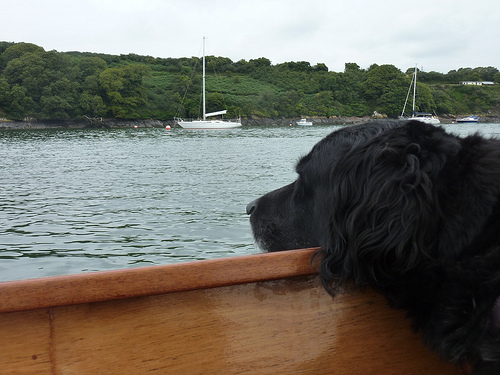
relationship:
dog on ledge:
[239, 115, 497, 365] [2, 245, 333, 314]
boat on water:
[5, 242, 464, 374] [0, 124, 498, 278]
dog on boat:
[239, 115, 497, 365] [5, 242, 464, 374]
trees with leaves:
[5, 46, 154, 119] [60, 89, 68, 90]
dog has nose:
[239, 115, 497, 365] [242, 194, 267, 222]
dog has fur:
[239, 115, 497, 365] [344, 161, 428, 242]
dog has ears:
[239, 115, 497, 365] [323, 144, 443, 289]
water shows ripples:
[0, 124, 498, 278] [14, 180, 166, 240]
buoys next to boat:
[127, 121, 174, 133] [176, 31, 246, 128]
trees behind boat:
[5, 46, 154, 119] [176, 31, 246, 128]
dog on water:
[239, 115, 497, 365] [0, 124, 498, 278]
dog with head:
[239, 115, 497, 365] [234, 113, 450, 286]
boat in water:
[176, 31, 246, 128] [0, 124, 498, 278]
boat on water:
[176, 31, 246, 128] [0, 124, 498, 278]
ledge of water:
[2, 245, 333, 314] [0, 124, 498, 278]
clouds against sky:
[231, 6, 485, 65] [1, 2, 500, 64]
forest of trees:
[3, 42, 475, 118] [5, 46, 154, 119]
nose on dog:
[242, 194, 267, 222] [239, 115, 497, 365]